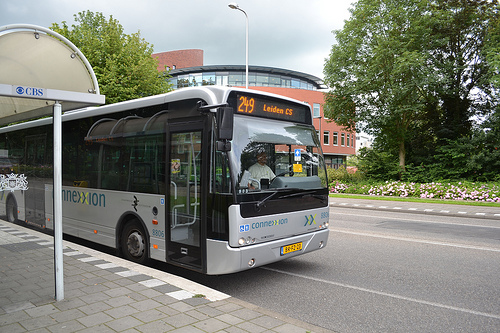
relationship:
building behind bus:
[299, 66, 361, 171] [2, 81, 337, 281]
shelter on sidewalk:
[2, 19, 107, 304] [0, 225, 244, 323]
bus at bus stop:
[2, 81, 337, 281] [2, 19, 107, 304]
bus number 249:
[2, 81, 337, 281] [233, 91, 259, 115]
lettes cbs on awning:
[16, 86, 44, 100] [0, 21, 111, 109]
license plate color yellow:
[282, 242, 304, 253] [278, 239, 306, 256]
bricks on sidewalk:
[5, 234, 158, 332] [0, 225, 244, 323]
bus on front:
[2, 81, 337, 281] [213, 82, 333, 266]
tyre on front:
[118, 212, 148, 265] [213, 82, 333, 266]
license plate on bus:
[282, 242, 304, 253] [2, 81, 337, 281]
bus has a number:
[2, 81, 337, 281] [233, 91, 259, 115]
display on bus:
[234, 94, 300, 120] [2, 81, 337, 281]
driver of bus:
[249, 145, 282, 185] [2, 81, 337, 281]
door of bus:
[166, 125, 206, 268] [2, 81, 337, 281]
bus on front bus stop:
[2, 81, 337, 281] [2, 19, 107, 304]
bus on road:
[2, 81, 337, 281] [321, 204, 485, 330]